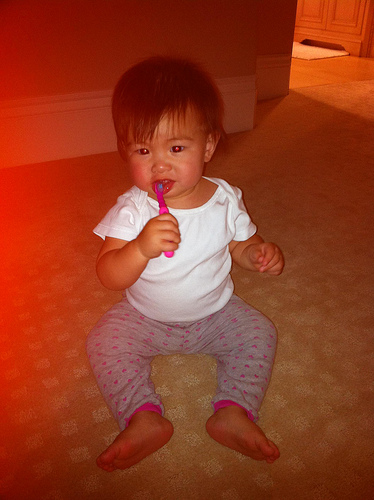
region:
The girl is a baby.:
[69, 55, 291, 447]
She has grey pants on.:
[86, 295, 285, 418]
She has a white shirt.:
[103, 196, 251, 311]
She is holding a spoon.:
[94, 136, 278, 305]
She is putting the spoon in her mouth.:
[127, 167, 195, 258]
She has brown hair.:
[94, 58, 229, 200]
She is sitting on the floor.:
[68, 44, 291, 443]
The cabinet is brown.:
[294, 1, 368, 58]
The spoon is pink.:
[144, 174, 188, 262]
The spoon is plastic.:
[145, 174, 184, 267]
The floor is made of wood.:
[289, 50, 373, 91]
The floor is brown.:
[286, 55, 373, 88]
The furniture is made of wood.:
[292, 1, 373, 57]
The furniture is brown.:
[291, 0, 372, 57]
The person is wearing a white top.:
[92, 174, 256, 324]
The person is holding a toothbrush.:
[147, 179, 182, 257]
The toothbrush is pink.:
[152, 180, 181, 259]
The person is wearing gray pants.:
[85, 293, 278, 430]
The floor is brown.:
[1, 76, 371, 497]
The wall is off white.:
[0, 0, 299, 103]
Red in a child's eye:
[174, 146, 180, 151]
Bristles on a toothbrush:
[156, 180, 165, 190]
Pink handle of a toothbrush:
[157, 201, 174, 259]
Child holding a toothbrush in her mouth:
[148, 177, 182, 261]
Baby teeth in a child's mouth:
[162, 178, 169, 183]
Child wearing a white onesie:
[101, 190, 254, 314]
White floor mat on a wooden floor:
[292, 39, 352, 64]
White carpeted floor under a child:
[19, 323, 365, 496]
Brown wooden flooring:
[291, 56, 371, 83]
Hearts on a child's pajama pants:
[84, 294, 280, 414]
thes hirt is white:
[111, 207, 237, 317]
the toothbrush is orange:
[145, 189, 178, 268]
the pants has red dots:
[94, 312, 186, 411]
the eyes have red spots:
[130, 141, 193, 160]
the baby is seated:
[91, 58, 301, 465]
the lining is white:
[211, 394, 245, 410]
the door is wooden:
[318, 17, 353, 33]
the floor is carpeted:
[300, 263, 372, 482]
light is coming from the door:
[306, 14, 372, 101]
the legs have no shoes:
[113, 412, 306, 488]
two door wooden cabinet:
[305, 0, 368, 60]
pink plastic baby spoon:
[147, 175, 191, 279]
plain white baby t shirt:
[88, 184, 264, 308]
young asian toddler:
[78, 43, 279, 456]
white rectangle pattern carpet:
[297, 277, 372, 488]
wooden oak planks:
[286, 59, 368, 83]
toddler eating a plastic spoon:
[76, 78, 281, 460]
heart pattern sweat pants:
[76, 302, 269, 410]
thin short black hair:
[100, 60, 224, 181]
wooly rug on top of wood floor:
[292, 40, 352, 64]